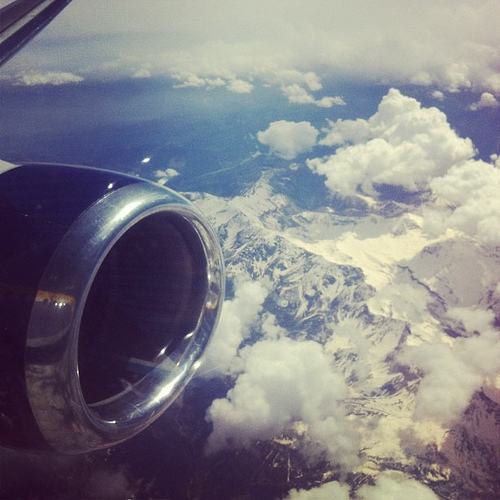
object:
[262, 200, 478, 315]
snowy valley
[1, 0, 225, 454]
airplane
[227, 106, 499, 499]
ground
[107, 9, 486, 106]
skys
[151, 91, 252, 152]
forest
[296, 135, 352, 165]
wall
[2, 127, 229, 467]
engine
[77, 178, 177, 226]
light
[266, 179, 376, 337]
mountain top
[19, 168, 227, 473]
trim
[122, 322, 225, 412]
reflection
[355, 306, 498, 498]
mountain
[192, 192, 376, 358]
mountain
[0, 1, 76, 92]
part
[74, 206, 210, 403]
inside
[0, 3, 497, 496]
clouds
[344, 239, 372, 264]
snow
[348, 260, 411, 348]
peaks